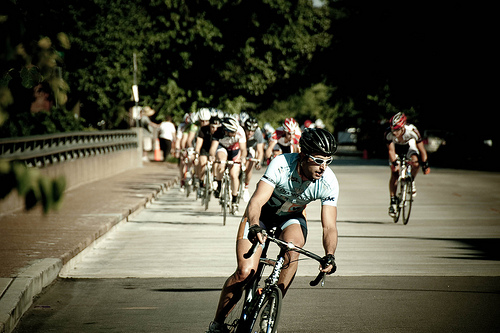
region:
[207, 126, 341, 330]
bicyclist closest to the camera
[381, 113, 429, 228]
bicycle rider wearing a red and silver helmet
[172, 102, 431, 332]
bicycle riders on a bridge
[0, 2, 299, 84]
green leaves on trees in the background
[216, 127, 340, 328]
man at the front of the bicyclists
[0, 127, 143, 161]
railing on the side of a bridge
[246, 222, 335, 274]
man's black gloves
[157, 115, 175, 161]
person wearing a white shirt and black pants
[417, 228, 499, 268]
shadows on the ground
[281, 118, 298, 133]
red and white bicycle helmet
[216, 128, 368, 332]
man leading the race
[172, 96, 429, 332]
group of men racing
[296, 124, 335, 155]
black helmet of lead racer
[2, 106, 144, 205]
railing along the bridge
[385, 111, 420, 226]
bicyclist separated from the pack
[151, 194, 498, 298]
shadows on the pavement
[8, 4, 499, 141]
trees behind the racers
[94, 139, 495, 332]
bridge racers are riding over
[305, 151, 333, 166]
white sunglasses of lead racer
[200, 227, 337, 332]
bicycle ridden by lead racer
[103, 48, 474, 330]
multiple people riding bikes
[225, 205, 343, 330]
this is a bike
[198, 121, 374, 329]
this is a man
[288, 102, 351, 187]
man wearing black helmet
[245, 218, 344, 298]
man holding on to handlebar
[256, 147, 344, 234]
man wearing white shirt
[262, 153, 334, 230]
dark graphics on shirt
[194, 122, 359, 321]
the man is leaning over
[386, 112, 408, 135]
person wearing red helmet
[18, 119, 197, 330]
brown sidewalk next to riders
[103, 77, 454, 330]
group of people riding bikes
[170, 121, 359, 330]
man riding a bike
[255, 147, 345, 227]
man wearing white shirt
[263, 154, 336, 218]
blue graphics on shirt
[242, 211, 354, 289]
man holding bike handles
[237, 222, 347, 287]
man wearing black gloves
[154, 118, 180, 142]
person wearing white shirt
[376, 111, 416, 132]
person wearing red helmet